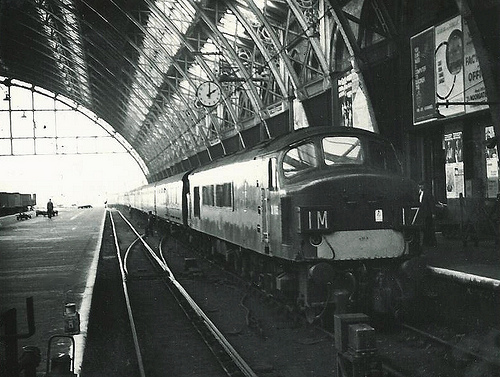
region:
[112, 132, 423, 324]
train on the track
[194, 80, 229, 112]
clock on the structure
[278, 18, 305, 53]
truss on the arch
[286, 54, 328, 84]
truss on the arch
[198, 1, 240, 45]
truss on the arch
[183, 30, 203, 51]
truss on the arch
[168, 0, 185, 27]
truss on the arch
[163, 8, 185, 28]
truss on the arch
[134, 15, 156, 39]
truss on the arch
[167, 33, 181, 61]
truss on the arch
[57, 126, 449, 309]
a train at the train station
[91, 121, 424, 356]
a train at the train station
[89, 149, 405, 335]
a train at the train station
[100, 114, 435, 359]
a train at the train station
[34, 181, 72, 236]
a man at the platform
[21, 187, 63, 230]
a man at the platform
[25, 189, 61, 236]
a man at the platform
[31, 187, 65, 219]
a man at the platform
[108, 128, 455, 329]
train on the tracks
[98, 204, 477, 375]
two sets of parallel train tracks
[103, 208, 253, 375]
no train on this set of tracks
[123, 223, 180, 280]
two sets of tracks merging into one set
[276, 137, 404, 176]
windows on the front of the train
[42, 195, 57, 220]
person standing on the concrete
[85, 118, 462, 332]
train in the station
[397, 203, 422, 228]
numbers on the front of the train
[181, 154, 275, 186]
light shining on the side of the train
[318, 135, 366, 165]
reflection in the window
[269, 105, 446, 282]
front of a train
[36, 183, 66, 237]
person walking on a ground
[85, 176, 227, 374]
a long rail road track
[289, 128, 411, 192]
windows of a train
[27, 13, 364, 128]
roof of a building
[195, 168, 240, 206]
windows of a train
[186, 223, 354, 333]
wheels of a train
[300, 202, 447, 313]
bumper of a train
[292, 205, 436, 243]
letters on a train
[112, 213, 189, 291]
split tracks on a ground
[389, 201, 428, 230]
numbers on the front of a train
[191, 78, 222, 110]
clock on the wall